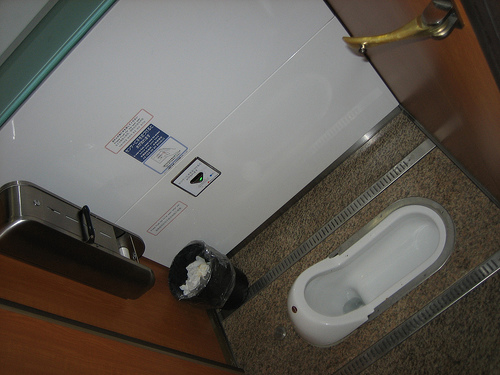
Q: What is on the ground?
A: A floor toilet.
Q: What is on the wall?
A: Notice signs.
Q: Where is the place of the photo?
A: A bathroom.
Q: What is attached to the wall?
A: Towel dispenser.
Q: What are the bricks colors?
A: White.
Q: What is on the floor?
A: Urinal.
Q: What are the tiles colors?
A: Brown.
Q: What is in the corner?
A: Trash can.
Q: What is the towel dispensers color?
A: Silver.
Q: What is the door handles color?
A: Gold.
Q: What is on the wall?
A: Blue beam.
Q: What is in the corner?
A: Black trash can.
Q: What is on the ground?
A: Floor urinal.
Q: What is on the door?
A: Handle.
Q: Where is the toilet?
A: On the floor.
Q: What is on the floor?
A: The toilet.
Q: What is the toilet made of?
A: Porcelain.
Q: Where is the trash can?
A: In the corner.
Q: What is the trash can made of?
A: Plastic.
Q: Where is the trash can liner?
A: In the trash can.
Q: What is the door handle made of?
A: Metal.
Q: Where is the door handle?
A: On the door.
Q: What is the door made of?
A: Wood.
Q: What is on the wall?
A: A toilet paper dispenser.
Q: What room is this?
A: Bathroom.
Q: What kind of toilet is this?
A: Squatty potty.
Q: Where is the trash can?
A: In the corner.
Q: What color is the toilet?
A: White.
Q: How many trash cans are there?
A: One.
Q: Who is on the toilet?
A: No one.